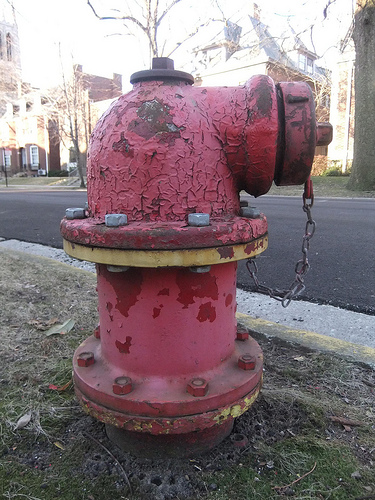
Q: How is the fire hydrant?
A: It is old.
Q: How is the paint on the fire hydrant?
A: It is chipping.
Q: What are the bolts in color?
A: Gray.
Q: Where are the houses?
A: Behind the fire hydrant.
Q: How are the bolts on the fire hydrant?
A: Red.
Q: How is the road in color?
A: Black.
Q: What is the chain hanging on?
A: Fire hydrant.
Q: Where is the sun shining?
A: On the buildings.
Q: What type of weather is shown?
A: Sunny.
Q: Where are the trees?
A: In front of the building.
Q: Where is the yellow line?
A: On the curb.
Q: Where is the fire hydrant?
A: In the ground.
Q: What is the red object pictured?
A: A fire hydrant.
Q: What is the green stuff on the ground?
A: Grass.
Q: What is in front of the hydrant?
A: A road.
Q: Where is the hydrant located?
A: In the ground.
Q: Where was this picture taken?
A: In a city.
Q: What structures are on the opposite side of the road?
A: Buildings.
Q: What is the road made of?
A: Asphalt.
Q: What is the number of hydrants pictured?
A: One.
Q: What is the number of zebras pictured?
A: Zeros.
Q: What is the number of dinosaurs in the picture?
A: Zero.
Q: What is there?
A: Fire hydrant.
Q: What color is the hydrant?
A: Red.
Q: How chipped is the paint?
A: Very chipped.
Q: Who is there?
A: No one.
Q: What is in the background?
A: Houses.